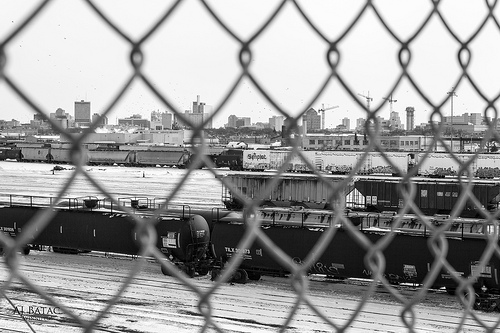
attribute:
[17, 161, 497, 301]
cars — train, circular, black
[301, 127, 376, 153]
windows — square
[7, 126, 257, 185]
cars — train, long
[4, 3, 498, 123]
sky — clear